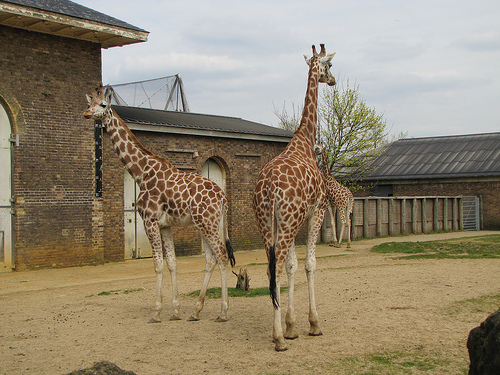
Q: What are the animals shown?
A: Giraffes.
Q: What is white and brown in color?
A: Giraffe.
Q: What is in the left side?
A: Giraffe house.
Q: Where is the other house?
A: Background.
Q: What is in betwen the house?
A: Tree.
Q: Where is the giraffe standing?
A: Ground.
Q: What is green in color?
A: Grass.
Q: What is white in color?
A: Door.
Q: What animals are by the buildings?
A: Giraffes.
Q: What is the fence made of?
A: Wood.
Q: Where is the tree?
A: Behind the fence.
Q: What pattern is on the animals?
A: Spots.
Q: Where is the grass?
A: On the ground.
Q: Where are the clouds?
A: In the sky.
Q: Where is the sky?
A: Above the buildings.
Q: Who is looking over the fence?
A: The farthest giraffe.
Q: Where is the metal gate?
A: Right of the fence.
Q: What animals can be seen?
A: Giraffes.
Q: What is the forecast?
A: Mostly cloudy.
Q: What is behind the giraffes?
A: A red brick building.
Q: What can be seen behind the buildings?
A: A tree.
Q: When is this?
A: Evening.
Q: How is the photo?
A: Clear.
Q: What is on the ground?
A: Grass.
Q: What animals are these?
A: Giraffes.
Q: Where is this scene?
A: At the zoo.